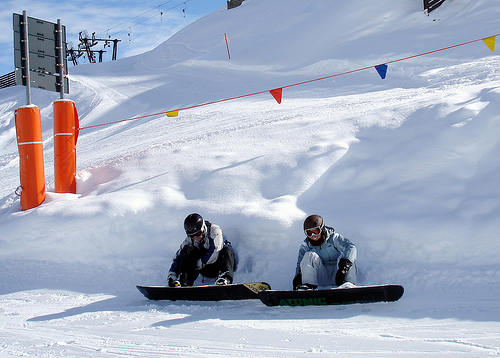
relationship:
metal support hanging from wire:
[74, 36, 119, 44] [121, 21, 148, 37]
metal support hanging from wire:
[67, 46, 105, 54] [134, 0, 168, 17]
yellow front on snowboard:
[239, 284, 269, 294] [137, 283, 271, 301]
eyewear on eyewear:
[304, 226, 321, 238] [304, 226, 321, 238]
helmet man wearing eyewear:
[293, 214, 357, 290] [304, 226, 321, 238]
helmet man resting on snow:
[293, 214, 357, 290] [2, 1, 498, 354]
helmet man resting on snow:
[166, 212, 239, 286] [2, 1, 498, 354]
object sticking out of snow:
[14, 102, 45, 209] [2, 1, 498, 354]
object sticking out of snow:
[52, 97, 79, 191] [41, 35, 494, 322]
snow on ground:
[2, 1, 498, 354] [0, 1, 497, 355]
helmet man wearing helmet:
[166, 212, 239, 286] [303, 214, 323, 231]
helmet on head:
[303, 214, 323, 231] [293, 211, 357, 292]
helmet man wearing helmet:
[166, 212, 239, 286] [185, 212, 200, 233]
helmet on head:
[185, 212, 200, 233] [166, 211, 237, 296]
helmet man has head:
[166, 212, 239, 286] [293, 211, 357, 292]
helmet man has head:
[166, 212, 239, 286] [166, 211, 237, 296]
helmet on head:
[183, 212, 204, 234] [183, 211, 209, 244]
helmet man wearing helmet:
[166, 212, 239, 286] [183, 212, 204, 234]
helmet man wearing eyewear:
[166, 212, 239, 286] [302, 225, 324, 247]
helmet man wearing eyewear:
[166, 212, 239, 286] [180, 227, 205, 240]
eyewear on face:
[302, 225, 324, 247] [301, 222, 326, 246]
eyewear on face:
[180, 227, 205, 240] [184, 226, 209, 245]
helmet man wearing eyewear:
[166, 212, 239, 286] [177, 229, 212, 241]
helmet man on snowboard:
[293, 214, 357, 290] [256, 282, 410, 312]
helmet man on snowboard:
[166, 212, 239, 286] [131, 277, 271, 304]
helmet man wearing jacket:
[293, 214, 357, 290] [302, 240, 357, 272]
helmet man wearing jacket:
[166, 212, 239, 286] [165, 233, 240, 275]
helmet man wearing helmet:
[293, 214, 357, 290] [303, 214, 323, 231]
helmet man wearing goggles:
[293, 214, 357, 290] [300, 224, 325, 241]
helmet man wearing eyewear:
[166, 212, 239, 286] [188, 230, 202, 238]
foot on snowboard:
[290, 280, 318, 290] [258, 283, 406, 306]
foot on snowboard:
[218, 273, 232, 286] [134, 280, 269, 303]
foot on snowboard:
[166, 277, 186, 290] [134, 280, 269, 303]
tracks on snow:
[12, 325, 280, 355] [2, 1, 498, 354]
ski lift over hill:
[66, 30, 128, 67] [0, 1, 500, 273]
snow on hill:
[2, 1, 498, 354] [0, 1, 500, 273]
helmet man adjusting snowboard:
[293, 214, 357, 290] [131, 277, 274, 311]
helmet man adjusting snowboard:
[293, 214, 357, 290] [257, 268, 419, 309]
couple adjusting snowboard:
[166, 212, 359, 292] [258, 284, 404, 306]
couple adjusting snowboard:
[166, 212, 359, 292] [134, 280, 269, 303]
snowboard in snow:
[258, 284, 404, 306] [157, 125, 491, 207]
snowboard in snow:
[134, 280, 269, 303] [157, 125, 491, 207]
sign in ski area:
[10, 10, 87, 211] [6, 0, 495, 356]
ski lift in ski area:
[66, 30, 120, 68] [0, 0, 500, 358]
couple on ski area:
[166, 212, 359, 292] [0, 0, 500, 358]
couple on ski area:
[139, 217, 264, 315] [0, 0, 500, 358]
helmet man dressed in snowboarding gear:
[166, 212, 239, 286] [294, 210, 363, 291]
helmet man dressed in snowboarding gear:
[293, 214, 357, 290] [166, 208, 242, 289]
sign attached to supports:
[12, 12, 69, 95] [4, 78, 101, 247]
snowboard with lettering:
[258, 286, 408, 307] [280, 298, 327, 306]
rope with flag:
[73, 31, 498, 133] [164, 103, 187, 123]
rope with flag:
[73, 31, 498, 133] [266, 85, 288, 105]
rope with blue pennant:
[73, 31, 498, 133] [374, 64, 388, 79]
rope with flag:
[73, 31, 498, 133] [479, 30, 496, 55]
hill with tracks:
[59, 77, 499, 213] [97, 78, 145, 115]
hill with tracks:
[59, 77, 499, 213] [159, 43, 181, 66]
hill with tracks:
[59, 77, 499, 213] [175, 35, 218, 62]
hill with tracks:
[59, 77, 499, 213] [376, 320, 498, 353]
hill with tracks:
[59, 77, 499, 213] [48, 332, 328, 356]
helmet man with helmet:
[166, 212, 239, 286] [181, 210, 213, 244]